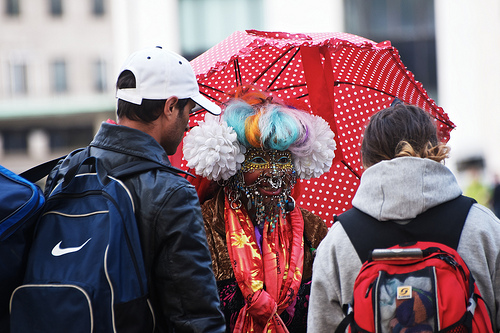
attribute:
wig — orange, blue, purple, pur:
[223, 90, 312, 151]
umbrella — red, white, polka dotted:
[165, 28, 456, 231]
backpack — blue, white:
[8, 157, 161, 332]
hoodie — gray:
[305, 156, 499, 332]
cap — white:
[115, 44, 221, 116]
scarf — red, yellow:
[225, 187, 305, 332]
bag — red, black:
[335, 239, 492, 332]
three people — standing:
[0, 43, 500, 331]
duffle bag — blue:
[1, 162, 46, 294]